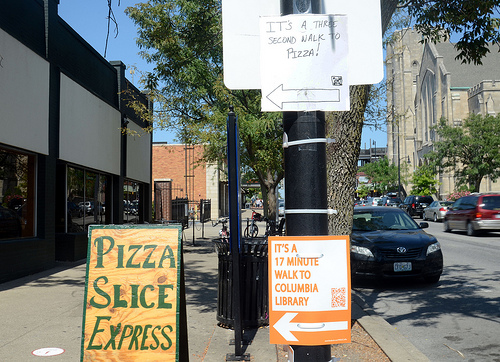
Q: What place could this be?
A: It is a sidewalk.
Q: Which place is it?
A: It is a sidewalk.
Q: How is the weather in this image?
A: It is clear.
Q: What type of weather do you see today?
A: It is clear.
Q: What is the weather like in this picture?
A: It is clear.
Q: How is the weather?
A: It is clear.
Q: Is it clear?
A: Yes, it is clear.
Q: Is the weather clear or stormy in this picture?
A: It is clear.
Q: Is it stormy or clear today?
A: It is clear.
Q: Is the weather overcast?
A: No, it is clear.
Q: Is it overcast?
A: No, it is clear.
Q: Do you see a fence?
A: Yes, there is a fence.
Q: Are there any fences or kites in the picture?
A: Yes, there is a fence.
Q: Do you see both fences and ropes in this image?
A: No, there is a fence but no ropes.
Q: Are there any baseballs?
A: No, there are no baseballs.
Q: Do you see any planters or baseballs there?
A: No, there are no baseballs or planters.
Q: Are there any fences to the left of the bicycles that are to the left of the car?
A: Yes, there is a fence to the left of the bicycles.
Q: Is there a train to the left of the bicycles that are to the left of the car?
A: No, there is a fence to the left of the bicycles.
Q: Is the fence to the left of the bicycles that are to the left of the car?
A: Yes, the fence is to the left of the bicycles.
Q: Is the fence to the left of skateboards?
A: No, the fence is to the left of the bicycles.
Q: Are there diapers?
A: No, there are no diapers.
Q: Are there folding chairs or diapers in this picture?
A: No, there are no diapers or folding chairs.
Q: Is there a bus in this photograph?
A: No, there are no buses.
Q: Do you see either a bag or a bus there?
A: No, there are no buses or bags.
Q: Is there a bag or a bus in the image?
A: No, there are no buses or bags.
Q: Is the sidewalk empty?
A: Yes, the sidewalk is empty.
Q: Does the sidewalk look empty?
A: Yes, the sidewalk is empty.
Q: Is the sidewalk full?
A: No, the sidewalk is empty.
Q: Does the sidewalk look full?
A: No, the sidewalk is empty.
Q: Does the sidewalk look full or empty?
A: The sidewalk is empty.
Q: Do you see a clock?
A: No, there are no clocks.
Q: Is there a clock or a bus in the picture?
A: No, there are no clocks or buses.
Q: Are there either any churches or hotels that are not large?
A: No, there is a church but it is large.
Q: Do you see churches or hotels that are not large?
A: No, there is a church but it is large.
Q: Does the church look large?
A: Yes, the church is large.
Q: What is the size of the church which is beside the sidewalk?
A: The church is large.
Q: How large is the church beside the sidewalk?
A: The church is large.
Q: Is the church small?
A: No, the church is large.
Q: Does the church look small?
A: No, the church is large.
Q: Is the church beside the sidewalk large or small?
A: The church is large.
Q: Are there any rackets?
A: No, there are no rackets.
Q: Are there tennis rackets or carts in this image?
A: No, there are no tennis rackets or carts.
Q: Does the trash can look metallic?
A: Yes, the trash can is metallic.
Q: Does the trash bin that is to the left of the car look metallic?
A: Yes, the trash can is metallic.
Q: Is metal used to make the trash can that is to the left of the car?
A: Yes, the garbage can is made of metal.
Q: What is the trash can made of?
A: The garbage can is made of metal.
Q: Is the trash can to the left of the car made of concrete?
A: No, the trash can is made of metal.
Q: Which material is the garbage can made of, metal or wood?
A: The garbage can is made of metal.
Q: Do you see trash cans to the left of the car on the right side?
A: Yes, there is a trash can to the left of the car.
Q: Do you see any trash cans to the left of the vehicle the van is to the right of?
A: Yes, there is a trash can to the left of the car.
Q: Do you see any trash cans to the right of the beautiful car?
A: No, the trash can is to the left of the car.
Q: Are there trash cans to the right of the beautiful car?
A: No, the trash can is to the left of the car.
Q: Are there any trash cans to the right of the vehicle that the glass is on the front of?
A: No, the trash can is to the left of the car.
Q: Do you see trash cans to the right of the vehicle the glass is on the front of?
A: No, the trash can is to the left of the car.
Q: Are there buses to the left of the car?
A: No, there is a trash can to the left of the car.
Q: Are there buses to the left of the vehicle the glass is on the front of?
A: No, there is a trash can to the left of the car.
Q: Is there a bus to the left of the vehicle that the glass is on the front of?
A: No, there is a trash can to the left of the car.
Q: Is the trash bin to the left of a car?
A: Yes, the trash bin is to the left of a car.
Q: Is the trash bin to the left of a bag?
A: No, the trash bin is to the left of a car.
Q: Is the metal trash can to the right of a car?
A: No, the trashcan is to the left of a car.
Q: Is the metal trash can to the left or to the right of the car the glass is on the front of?
A: The trashcan is to the left of the car.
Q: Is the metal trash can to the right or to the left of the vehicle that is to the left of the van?
A: The trashcan is to the left of the car.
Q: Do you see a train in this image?
A: No, there are no trains.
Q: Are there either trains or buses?
A: No, there are no trains or buses.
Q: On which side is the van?
A: The van is on the right of the image.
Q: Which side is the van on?
A: The van is on the right of the image.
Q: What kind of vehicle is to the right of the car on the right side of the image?
A: The vehicle is a van.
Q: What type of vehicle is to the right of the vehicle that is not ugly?
A: The vehicle is a van.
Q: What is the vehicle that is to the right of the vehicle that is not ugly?
A: The vehicle is a van.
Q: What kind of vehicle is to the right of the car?
A: The vehicle is a van.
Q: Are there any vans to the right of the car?
A: Yes, there is a van to the right of the car.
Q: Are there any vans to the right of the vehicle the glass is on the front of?
A: Yes, there is a van to the right of the car.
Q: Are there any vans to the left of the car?
A: No, the van is to the right of the car.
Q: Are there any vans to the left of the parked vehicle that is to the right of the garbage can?
A: No, the van is to the right of the car.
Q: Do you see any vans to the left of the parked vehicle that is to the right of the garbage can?
A: No, the van is to the right of the car.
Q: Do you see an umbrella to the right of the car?
A: No, there is a van to the right of the car.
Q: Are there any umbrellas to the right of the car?
A: No, there is a van to the right of the car.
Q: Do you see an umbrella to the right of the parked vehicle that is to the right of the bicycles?
A: No, there is a van to the right of the car.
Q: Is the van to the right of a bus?
A: No, the van is to the right of a car.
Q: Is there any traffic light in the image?
A: No, there are no traffic lights.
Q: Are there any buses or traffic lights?
A: No, there are no traffic lights or buses.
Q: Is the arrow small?
A: Yes, the arrow is small.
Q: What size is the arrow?
A: The arrow is small.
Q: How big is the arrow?
A: The arrow is small.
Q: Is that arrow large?
A: No, the arrow is small.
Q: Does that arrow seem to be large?
A: No, the arrow is small.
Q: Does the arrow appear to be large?
A: No, the arrow is small.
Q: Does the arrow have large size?
A: No, the arrow is small.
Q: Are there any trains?
A: No, there are no trains.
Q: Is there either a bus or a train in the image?
A: No, there are no trains or buses.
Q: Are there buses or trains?
A: No, there are no trains or buses.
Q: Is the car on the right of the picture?
A: Yes, the car is on the right of the image.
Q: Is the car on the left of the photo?
A: No, the car is on the right of the image.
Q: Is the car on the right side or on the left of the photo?
A: The car is on the right of the image.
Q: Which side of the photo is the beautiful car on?
A: The car is on the right of the image.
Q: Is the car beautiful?
A: Yes, the car is beautiful.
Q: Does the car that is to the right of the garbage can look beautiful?
A: Yes, the car is beautiful.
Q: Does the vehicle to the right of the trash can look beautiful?
A: Yes, the car is beautiful.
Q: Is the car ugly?
A: No, the car is beautiful.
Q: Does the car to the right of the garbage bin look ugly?
A: No, the car is beautiful.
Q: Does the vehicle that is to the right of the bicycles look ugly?
A: No, the car is beautiful.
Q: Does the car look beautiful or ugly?
A: The car is beautiful.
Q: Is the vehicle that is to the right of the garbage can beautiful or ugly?
A: The car is beautiful.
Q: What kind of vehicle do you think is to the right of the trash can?
A: The vehicle is a car.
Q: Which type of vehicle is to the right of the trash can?
A: The vehicle is a car.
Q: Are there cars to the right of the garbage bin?
A: Yes, there is a car to the right of the garbage bin.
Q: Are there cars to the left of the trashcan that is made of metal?
A: No, the car is to the right of the garbage bin.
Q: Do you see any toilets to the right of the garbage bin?
A: No, there is a car to the right of the garbage bin.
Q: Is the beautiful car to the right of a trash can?
A: Yes, the car is to the right of a trash can.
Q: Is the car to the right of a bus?
A: No, the car is to the right of a trash can.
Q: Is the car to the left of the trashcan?
A: No, the car is to the right of the trashcan.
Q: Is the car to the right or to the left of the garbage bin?
A: The car is to the right of the garbage bin.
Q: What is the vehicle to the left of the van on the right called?
A: The vehicle is a car.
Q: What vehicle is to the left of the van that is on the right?
A: The vehicle is a car.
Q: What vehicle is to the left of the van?
A: The vehicle is a car.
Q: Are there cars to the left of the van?
A: Yes, there is a car to the left of the van.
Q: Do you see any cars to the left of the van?
A: Yes, there is a car to the left of the van.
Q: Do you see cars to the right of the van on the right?
A: No, the car is to the left of the van.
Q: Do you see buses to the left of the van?
A: No, there is a car to the left of the van.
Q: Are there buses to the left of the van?
A: No, there is a car to the left of the van.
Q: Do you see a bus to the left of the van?
A: No, there is a car to the left of the van.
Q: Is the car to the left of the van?
A: Yes, the car is to the left of the van.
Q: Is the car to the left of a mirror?
A: No, the car is to the left of the van.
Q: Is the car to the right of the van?
A: No, the car is to the left of the van.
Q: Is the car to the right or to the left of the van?
A: The car is to the left of the van.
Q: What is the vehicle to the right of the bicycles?
A: The vehicle is a car.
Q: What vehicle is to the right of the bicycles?
A: The vehicle is a car.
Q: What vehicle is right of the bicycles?
A: The vehicle is a car.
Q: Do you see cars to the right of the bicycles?
A: Yes, there is a car to the right of the bicycles.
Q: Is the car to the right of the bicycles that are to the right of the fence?
A: Yes, the car is to the right of the bicycles.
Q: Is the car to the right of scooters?
A: No, the car is to the right of the bicycles.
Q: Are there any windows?
A: Yes, there are windows.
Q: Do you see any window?
A: Yes, there are windows.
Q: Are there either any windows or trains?
A: Yes, there are windows.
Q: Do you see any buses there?
A: No, there are no buses.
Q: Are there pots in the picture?
A: No, there are no pots.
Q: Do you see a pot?
A: No, there are no pots.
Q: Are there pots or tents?
A: No, there are no pots or tents.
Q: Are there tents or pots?
A: No, there are no pots or tents.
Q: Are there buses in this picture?
A: No, there are no buses.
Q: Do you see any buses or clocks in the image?
A: No, there are no buses or clocks.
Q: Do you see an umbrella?
A: No, there are no umbrellas.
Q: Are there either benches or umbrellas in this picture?
A: No, there are no umbrellas or benches.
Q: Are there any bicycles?
A: Yes, there are bicycles.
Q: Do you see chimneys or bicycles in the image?
A: Yes, there are bicycles.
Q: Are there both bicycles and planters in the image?
A: No, there are bicycles but no planters.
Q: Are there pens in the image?
A: No, there are no pens.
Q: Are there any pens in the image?
A: No, there are no pens.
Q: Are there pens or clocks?
A: No, there are no pens or clocks.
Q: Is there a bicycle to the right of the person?
A: Yes, there are bicycles to the right of the person.